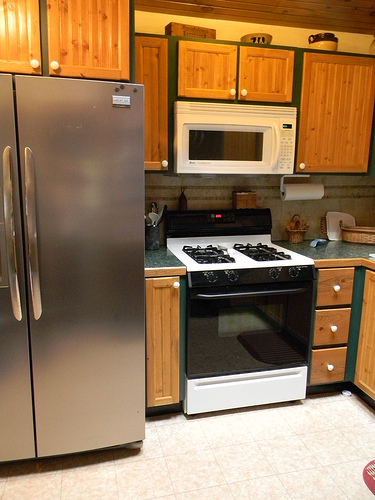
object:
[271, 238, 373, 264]
counter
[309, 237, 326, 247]
holder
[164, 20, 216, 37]
box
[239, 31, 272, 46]
pot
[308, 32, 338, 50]
bowl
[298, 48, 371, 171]
cabinet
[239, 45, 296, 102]
cabinet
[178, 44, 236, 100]
cabinet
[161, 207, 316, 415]
oven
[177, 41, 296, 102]
cabinets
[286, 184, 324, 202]
towels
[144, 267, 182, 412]
drawers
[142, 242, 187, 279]
counter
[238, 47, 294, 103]
door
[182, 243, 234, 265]
burner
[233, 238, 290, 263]
burner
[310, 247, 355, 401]
drawers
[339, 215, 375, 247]
basket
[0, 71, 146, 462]
fridge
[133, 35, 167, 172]
cabinet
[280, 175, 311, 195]
dispenser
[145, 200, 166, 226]
utensils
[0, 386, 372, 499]
floor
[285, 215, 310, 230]
utensils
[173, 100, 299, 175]
microwave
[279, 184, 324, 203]
paper towel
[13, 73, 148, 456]
door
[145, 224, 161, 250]
container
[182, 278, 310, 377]
door